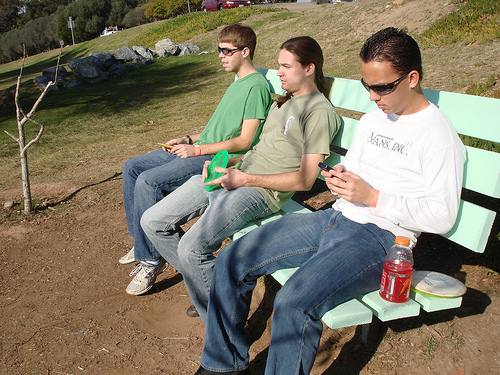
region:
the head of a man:
[338, 24, 435, 126]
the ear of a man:
[391, 63, 431, 100]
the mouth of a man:
[361, 92, 401, 129]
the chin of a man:
[366, 92, 401, 124]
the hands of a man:
[300, 155, 367, 221]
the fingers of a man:
[300, 150, 371, 207]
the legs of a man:
[175, 223, 403, 341]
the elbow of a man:
[278, 169, 331, 216]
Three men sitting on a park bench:
[107, 20, 477, 370]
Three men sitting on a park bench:
[113, 18, 480, 373]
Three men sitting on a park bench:
[113, 20, 472, 367]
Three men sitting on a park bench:
[114, 18, 486, 371]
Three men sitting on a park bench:
[111, 17, 486, 365]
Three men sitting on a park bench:
[109, 19, 479, 363]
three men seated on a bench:
[175, 35, 470, 347]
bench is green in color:
[469, 87, 496, 282]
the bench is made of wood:
[452, 108, 465, 307]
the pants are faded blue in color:
[259, 202, 346, 338]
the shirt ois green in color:
[216, 79, 271, 136]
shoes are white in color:
[103, 240, 161, 292]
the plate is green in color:
[207, 154, 242, 191]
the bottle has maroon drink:
[378, 242, 414, 327]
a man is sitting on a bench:
[197, 23, 467, 373]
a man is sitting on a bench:
[140, 37, 339, 338]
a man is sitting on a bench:
[118, 24, 263, 295]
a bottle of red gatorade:
[375, 236, 413, 298]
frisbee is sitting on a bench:
[411, 268, 468, 299]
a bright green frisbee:
[200, 151, 227, 192]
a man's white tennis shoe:
[125, 261, 170, 298]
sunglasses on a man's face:
[215, 43, 240, 53]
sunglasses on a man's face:
[358, 73, 408, 94]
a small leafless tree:
[8, 47, 60, 212]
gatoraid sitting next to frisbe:
[367, 222, 472, 314]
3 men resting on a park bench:
[112, 10, 487, 359]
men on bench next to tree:
[6, 66, 335, 219]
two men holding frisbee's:
[152, 18, 319, 205]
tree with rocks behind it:
[0, 41, 112, 218]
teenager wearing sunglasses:
[205, 15, 260, 80]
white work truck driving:
[94, 15, 133, 43]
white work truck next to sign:
[62, 13, 127, 45]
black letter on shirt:
[366, 128, 381, 144]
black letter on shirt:
[371, 130, 381, 147]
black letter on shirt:
[380, 136, 387, 147]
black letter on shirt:
[382, 139, 389, 148]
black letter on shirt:
[389, 141, 396, 152]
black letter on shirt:
[393, 140, 403, 151]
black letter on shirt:
[399, 145, 407, 157]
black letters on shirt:
[364, 127, 391, 149]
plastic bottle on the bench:
[379, 235, 412, 305]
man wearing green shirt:
[109, 19, 256, 274]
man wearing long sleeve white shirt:
[210, 26, 460, 373]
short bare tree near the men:
[11, 44, 79, 212]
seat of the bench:
[232, 193, 465, 328]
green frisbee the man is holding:
[203, 148, 225, 185]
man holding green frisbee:
[141, 27, 327, 300]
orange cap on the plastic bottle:
[394, 235, 411, 248]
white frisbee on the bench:
[411, 267, 459, 297]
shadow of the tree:
[43, 163, 120, 206]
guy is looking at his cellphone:
[315, 29, 416, 200]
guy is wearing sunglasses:
[354, 25, 420, 115]